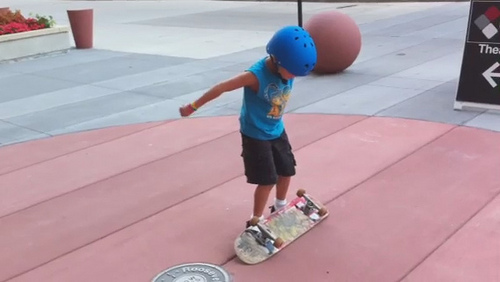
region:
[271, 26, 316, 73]
the boy has a helmet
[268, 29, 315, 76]
the helmet is blue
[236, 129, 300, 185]
the boy wears shorts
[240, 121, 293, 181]
the shorts are black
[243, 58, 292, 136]
the boy wears a blue shirt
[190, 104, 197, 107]
the boy has a bracelet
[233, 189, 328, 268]
the boy has a skateboard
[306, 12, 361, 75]
a red ball on ground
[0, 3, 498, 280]
scene takes place outdoors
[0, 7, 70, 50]
the flowers are planted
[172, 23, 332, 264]
a boy wearing a light blue helmet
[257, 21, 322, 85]
a blue skateboarding helmet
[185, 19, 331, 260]
a boy looking down at a skateboard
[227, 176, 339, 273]
a skateboard turned upside down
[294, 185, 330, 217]
the rear wheels of a skateboard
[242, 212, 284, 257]
the front wheels of a skateboard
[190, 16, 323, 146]
a boy wearing a blue shirt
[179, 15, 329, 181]
a boy wearing black shorts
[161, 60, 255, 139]
the arm of a boy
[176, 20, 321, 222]
young boy wearing blue helmet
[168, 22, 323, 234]
young boy in blue tank top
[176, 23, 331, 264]
young boy with skate board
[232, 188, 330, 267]
skate board turned over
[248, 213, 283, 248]
wheels of skate board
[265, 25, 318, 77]
blue helmet on boy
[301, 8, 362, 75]
large red ball on sidewalk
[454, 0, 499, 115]
sign board on sidewalk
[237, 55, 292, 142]
blue tank top with graphic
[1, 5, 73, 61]
planter with red flowers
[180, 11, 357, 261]
this is a child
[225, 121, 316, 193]
child wearing black pants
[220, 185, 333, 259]
this is a skatboard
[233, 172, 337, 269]
the skateboard is flipped over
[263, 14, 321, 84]
child wearing blue helmet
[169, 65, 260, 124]
child has arm extended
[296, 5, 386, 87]
red ball in background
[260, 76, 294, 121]
yellow print on shirt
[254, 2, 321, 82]
this is a helmet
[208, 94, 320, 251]
this is a skateboarder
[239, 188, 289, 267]
these are some wheels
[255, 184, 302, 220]
this is a sock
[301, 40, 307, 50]
hole in blue helmet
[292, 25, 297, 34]
hole in blue helmet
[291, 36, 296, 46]
hole in blue helmet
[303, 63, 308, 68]
hole in blue helmet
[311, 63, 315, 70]
hole in blue helmet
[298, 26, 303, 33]
hole in blue helmet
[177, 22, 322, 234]
a kid wearing a blue helmet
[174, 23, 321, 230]
a kid wearing a blue shirt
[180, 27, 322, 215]
a kid wearing shorts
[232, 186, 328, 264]
a skateboard turned upside down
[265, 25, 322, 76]
a blue protective helmet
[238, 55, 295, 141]
a blue sleeveless shirt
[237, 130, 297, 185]
a pair of dark color shorts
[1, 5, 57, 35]
a bed of flowers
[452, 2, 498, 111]
a sign with an arrow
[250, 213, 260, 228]
wheel on the wooden skateboard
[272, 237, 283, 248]
wheel on the wooden skateboard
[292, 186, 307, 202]
wheel on the wooden skateboard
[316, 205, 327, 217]
wheel on the wooden skateboard